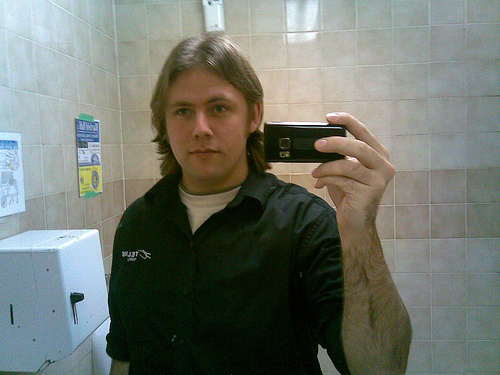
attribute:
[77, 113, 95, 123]
tape — green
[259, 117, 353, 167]
cellphone — black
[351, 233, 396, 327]
hair — brown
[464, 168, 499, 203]
tile — square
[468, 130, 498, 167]
tile — square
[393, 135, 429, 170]
tile — square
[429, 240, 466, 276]
tile — square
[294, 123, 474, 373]
arm — hairy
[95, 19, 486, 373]
person — taking selfie photo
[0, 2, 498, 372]
bathroom — walls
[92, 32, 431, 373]
man — taking selfie photo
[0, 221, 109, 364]
dispenser — paper towel dispenser, white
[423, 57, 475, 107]
tile — square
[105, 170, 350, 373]
shirt — black, button down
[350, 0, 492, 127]
tile wall — two tone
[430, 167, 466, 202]
tile — square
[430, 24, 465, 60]
tile — square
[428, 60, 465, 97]
tile — square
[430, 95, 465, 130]
tile — square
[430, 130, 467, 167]
tile — square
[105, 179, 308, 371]
shirt — black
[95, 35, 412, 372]
person — taking photo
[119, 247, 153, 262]
writing — white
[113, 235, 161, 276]
logo — white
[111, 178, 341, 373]
tshirt — white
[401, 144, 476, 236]
tiles — color